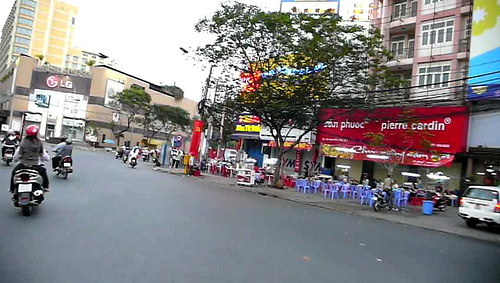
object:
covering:
[317, 106, 470, 155]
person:
[171, 148, 181, 169]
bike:
[9, 165, 50, 216]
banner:
[320, 141, 454, 168]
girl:
[9, 125, 50, 191]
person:
[119, 148, 124, 159]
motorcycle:
[122, 156, 127, 162]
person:
[52, 139, 74, 170]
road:
[2, 142, 499, 279]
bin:
[422, 200, 434, 215]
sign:
[442, 117, 452, 125]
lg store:
[24, 71, 88, 141]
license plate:
[17, 184, 32, 192]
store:
[321, 103, 467, 199]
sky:
[83, 0, 181, 64]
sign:
[324, 118, 369, 131]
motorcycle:
[373, 192, 392, 212]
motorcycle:
[2, 149, 14, 166]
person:
[188, 154, 195, 176]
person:
[1, 131, 20, 157]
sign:
[192, 126, 202, 133]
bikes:
[50, 150, 73, 179]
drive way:
[376, 221, 498, 249]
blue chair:
[295, 178, 410, 207]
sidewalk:
[277, 175, 463, 232]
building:
[368, 0, 500, 197]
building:
[90, 66, 199, 147]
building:
[0, 1, 91, 138]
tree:
[177, 1, 409, 187]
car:
[457, 185, 500, 228]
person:
[128, 146, 139, 162]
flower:
[470, 6, 487, 24]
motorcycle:
[130, 157, 137, 168]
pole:
[206, 67, 214, 100]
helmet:
[26, 124, 41, 136]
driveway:
[443, 225, 497, 239]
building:
[273, 0, 339, 175]